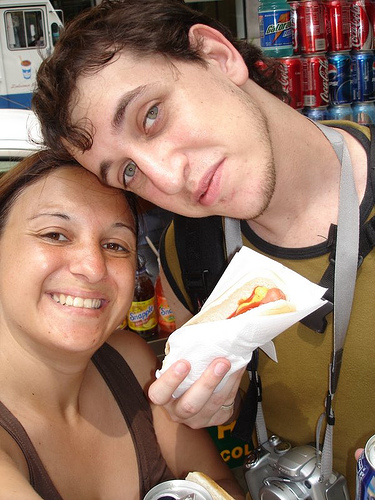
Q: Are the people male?
A: No, they are both male and female.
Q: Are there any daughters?
A: No, there are no daughters.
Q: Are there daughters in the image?
A: No, there are no daughters.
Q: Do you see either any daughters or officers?
A: No, there are no daughters or officers.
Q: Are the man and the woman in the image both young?
A: Yes, both the man and the woman are young.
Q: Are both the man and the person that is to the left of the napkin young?
A: Yes, both the man and the woman are young.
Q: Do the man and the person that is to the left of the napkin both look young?
A: Yes, both the man and the woman are young.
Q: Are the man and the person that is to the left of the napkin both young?
A: Yes, both the man and the woman are young.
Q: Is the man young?
A: Yes, the man is young.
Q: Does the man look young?
A: Yes, the man is young.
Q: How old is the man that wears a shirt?
A: The man is young.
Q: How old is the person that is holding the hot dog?
A: The man is young.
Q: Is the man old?
A: No, the man is young.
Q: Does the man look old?
A: No, the man is young.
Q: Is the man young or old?
A: The man is young.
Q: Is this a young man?
A: Yes, this is a young man.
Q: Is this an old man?
A: No, this is a young man.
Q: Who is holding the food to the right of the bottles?
A: The man is holding the hot dog.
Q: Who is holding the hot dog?
A: The man is holding the hot dog.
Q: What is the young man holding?
A: The man is holding the hot dog.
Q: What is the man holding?
A: The man is holding the hot dog.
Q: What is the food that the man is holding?
A: The food is a hot dog.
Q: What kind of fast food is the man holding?
A: The man is holding the hot dog.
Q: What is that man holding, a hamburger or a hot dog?
A: The man is holding a hot dog.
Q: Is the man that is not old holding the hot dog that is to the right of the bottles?
A: Yes, the man is holding the hot dog.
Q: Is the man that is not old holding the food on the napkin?
A: Yes, the man is holding the hot dog.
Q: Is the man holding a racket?
A: No, the man is holding the hot dog.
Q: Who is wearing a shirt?
A: The man is wearing a shirt.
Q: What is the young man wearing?
A: The man is wearing a shirt.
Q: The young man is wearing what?
A: The man is wearing a shirt.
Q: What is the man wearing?
A: The man is wearing a shirt.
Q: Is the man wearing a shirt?
A: Yes, the man is wearing a shirt.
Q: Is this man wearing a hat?
A: No, the man is wearing a shirt.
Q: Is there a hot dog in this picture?
A: Yes, there is a hot dog.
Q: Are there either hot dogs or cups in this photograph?
A: Yes, there is a hot dog.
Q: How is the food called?
A: The food is a hot dog.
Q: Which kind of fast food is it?
A: The food is a hot dog.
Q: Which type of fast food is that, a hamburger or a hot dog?
A: This is a hot dog.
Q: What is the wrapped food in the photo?
A: The food is a hot dog.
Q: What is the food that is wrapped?
A: The food is a hot dog.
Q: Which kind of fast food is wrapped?
A: The fast food is a hot dog.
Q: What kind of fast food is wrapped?
A: The fast food is a hot dog.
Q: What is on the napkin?
A: The hot dog is on the napkin.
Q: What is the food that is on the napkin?
A: The food is a hot dog.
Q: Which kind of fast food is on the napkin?
A: The food is a hot dog.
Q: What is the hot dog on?
A: The hot dog is on the napkin.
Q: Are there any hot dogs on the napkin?
A: Yes, there is a hot dog on the napkin.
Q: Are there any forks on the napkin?
A: No, there is a hot dog on the napkin.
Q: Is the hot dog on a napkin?
A: Yes, the hot dog is on a napkin.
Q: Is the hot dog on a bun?
A: No, the hot dog is on a napkin.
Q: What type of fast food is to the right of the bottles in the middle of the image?
A: The food is a hot dog.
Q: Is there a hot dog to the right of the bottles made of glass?
A: Yes, there is a hot dog to the right of the bottles.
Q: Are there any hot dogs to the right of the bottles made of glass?
A: Yes, there is a hot dog to the right of the bottles.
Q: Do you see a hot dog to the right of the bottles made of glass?
A: Yes, there is a hot dog to the right of the bottles.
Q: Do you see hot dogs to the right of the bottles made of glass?
A: Yes, there is a hot dog to the right of the bottles.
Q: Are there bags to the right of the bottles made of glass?
A: No, there is a hot dog to the right of the bottles.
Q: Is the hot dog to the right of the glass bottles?
A: Yes, the hot dog is to the right of the bottles.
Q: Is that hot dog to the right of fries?
A: No, the hot dog is to the right of the bottles.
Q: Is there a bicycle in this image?
A: No, there are no bicycles.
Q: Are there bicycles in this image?
A: No, there are no bicycles.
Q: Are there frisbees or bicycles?
A: No, there are no bicycles or frisbees.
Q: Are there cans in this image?
A: Yes, there is a can.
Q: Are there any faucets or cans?
A: Yes, there is a can.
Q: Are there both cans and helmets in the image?
A: No, there is a can but no helmets.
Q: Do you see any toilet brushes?
A: No, there are no toilet brushes.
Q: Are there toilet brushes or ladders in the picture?
A: No, there are no toilet brushes or ladders.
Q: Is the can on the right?
A: Yes, the can is on the right of the image.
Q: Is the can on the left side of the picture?
A: No, the can is on the right of the image.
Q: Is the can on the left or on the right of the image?
A: The can is on the right of the image.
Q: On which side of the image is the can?
A: The can is on the right of the image.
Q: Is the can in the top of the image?
A: Yes, the can is in the top of the image.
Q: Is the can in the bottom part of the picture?
A: No, the can is in the top of the image.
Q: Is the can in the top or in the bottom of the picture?
A: The can is in the top of the image.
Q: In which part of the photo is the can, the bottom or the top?
A: The can is in the top of the image.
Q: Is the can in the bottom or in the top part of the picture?
A: The can is in the top of the image.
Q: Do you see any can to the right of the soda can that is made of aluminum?
A: Yes, there is a can to the right of the soda can.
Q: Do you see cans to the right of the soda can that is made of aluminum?
A: Yes, there is a can to the right of the soda can.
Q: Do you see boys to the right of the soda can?
A: No, there is a can to the right of the soda can.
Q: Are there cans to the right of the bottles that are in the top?
A: Yes, there is a can to the right of the bottles.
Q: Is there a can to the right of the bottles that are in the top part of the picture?
A: Yes, there is a can to the right of the bottles.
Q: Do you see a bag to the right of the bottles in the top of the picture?
A: No, there is a can to the right of the bottles.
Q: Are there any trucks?
A: Yes, there is a truck.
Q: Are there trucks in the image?
A: Yes, there is a truck.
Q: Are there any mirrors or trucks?
A: Yes, there is a truck.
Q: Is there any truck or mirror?
A: Yes, there is a truck.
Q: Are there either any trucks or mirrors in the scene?
A: Yes, there is a truck.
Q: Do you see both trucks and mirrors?
A: No, there is a truck but no mirrors.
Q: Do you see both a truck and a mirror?
A: No, there is a truck but no mirrors.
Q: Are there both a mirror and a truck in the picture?
A: No, there is a truck but no mirrors.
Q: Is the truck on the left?
A: Yes, the truck is on the left of the image.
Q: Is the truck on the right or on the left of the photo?
A: The truck is on the left of the image.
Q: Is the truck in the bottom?
A: No, the truck is in the top of the image.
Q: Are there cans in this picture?
A: Yes, there is a can.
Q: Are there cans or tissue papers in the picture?
A: Yes, there is a can.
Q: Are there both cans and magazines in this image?
A: No, there is a can but no magazines.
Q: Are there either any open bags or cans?
A: Yes, there is an open can.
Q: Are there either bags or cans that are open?
A: Yes, the can is open.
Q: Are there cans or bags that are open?
A: Yes, the can is open.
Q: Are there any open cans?
A: Yes, there is an open can.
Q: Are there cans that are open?
A: Yes, there is a can that is open.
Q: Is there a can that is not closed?
A: Yes, there is a open can.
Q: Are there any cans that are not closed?
A: Yes, there is a open can.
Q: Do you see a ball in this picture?
A: No, there are no balls.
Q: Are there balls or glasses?
A: No, there are no balls or glasses.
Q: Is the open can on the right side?
A: Yes, the can is on the right of the image.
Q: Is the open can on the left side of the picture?
A: No, the can is on the right of the image.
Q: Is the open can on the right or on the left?
A: The can is on the right of the image.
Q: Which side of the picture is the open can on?
A: The can is on the right of the image.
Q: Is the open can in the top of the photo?
A: Yes, the can is in the top of the image.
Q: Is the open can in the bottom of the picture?
A: No, the can is in the top of the image.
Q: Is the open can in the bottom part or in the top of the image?
A: The can is in the top of the image.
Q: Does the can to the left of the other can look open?
A: Yes, the can is open.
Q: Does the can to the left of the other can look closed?
A: No, the can is open.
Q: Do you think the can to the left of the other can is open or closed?
A: The can is open.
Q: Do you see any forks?
A: No, there are no forks.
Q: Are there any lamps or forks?
A: No, there are no forks or lamps.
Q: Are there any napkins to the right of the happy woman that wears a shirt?
A: Yes, there is a napkin to the right of the woman.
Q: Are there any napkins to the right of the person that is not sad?
A: Yes, there is a napkin to the right of the woman.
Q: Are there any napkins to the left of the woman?
A: No, the napkin is to the right of the woman.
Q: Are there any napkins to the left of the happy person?
A: No, the napkin is to the right of the woman.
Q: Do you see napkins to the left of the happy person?
A: No, the napkin is to the right of the woman.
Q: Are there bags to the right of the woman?
A: No, there is a napkin to the right of the woman.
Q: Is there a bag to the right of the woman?
A: No, there is a napkin to the right of the woman.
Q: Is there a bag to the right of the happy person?
A: No, there is a napkin to the right of the woman.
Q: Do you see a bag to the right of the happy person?
A: No, there is a napkin to the right of the woman.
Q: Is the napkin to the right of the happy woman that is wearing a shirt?
A: Yes, the napkin is to the right of the woman.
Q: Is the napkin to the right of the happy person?
A: Yes, the napkin is to the right of the woman.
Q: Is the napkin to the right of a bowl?
A: No, the napkin is to the right of the woman.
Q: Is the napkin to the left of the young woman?
A: No, the napkin is to the right of the woman.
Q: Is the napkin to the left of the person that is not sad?
A: No, the napkin is to the right of the woman.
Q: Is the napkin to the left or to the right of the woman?
A: The napkin is to the right of the woman.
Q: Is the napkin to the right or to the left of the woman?
A: The napkin is to the right of the woman.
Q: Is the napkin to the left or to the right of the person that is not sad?
A: The napkin is to the right of the woman.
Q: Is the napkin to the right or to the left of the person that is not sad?
A: The napkin is to the right of the woman.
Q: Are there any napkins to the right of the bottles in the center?
A: Yes, there is a napkin to the right of the bottles.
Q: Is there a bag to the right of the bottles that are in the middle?
A: No, there is a napkin to the right of the bottles.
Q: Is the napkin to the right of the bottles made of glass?
A: Yes, the napkin is to the right of the bottles.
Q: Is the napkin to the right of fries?
A: No, the napkin is to the right of the bottles.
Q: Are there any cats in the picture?
A: No, there are no cats.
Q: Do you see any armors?
A: No, there are no armors.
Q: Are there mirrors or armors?
A: No, there are no armors or mirrors.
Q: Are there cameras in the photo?
A: Yes, there is a camera.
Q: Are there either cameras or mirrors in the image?
A: Yes, there is a camera.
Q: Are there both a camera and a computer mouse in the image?
A: No, there is a camera but no computer mice.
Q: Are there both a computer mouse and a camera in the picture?
A: No, there is a camera but no computer mice.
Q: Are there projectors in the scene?
A: No, there are no projectors.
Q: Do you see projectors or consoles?
A: No, there are no projectors or consoles.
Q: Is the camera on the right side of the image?
A: Yes, the camera is on the right of the image.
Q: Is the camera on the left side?
A: No, the camera is on the right of the image.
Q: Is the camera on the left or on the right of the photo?
A: The camera is on the right of the image.